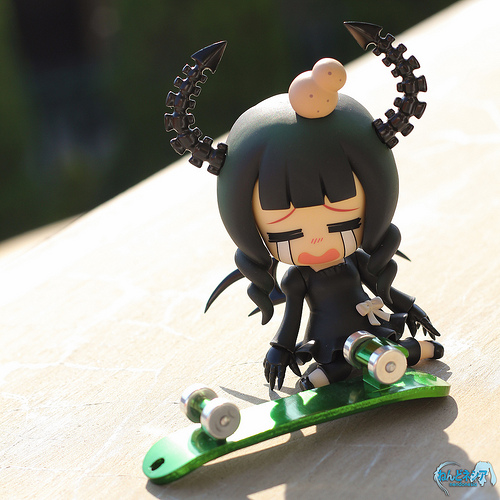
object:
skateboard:
[141, 329, 451, 485]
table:
[0, 1, 499, 499]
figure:
[164, 20, 445, 393]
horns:
[343, 20, 427, 150]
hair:
[203, 92, 409, 325]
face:
[251, 171, 365, 266]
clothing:
[270, 250, 421, 385]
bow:
[355, 296, 394, 326]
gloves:
[263, 345, 302, 391]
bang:
[258, 148, 356, 211]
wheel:
[200, 398, 240, 439]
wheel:
[179, 383, 219, 423]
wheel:
[367, 345, 407, 384]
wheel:
[343, 330, 377, 369]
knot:
[288, 57, 347, 119]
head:
[216, 92, 399, 266]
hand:
[406, 304, 441, 341]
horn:
[163, 40, 228, 176]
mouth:
[298, 248, 340, 264]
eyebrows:
[267, 208, 296, 225]